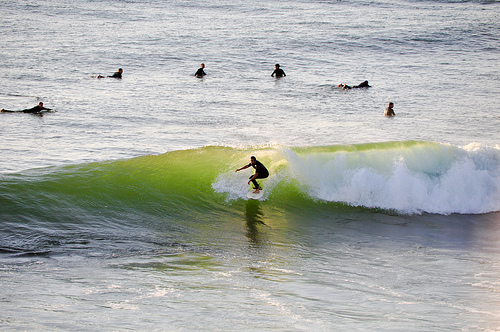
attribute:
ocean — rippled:
[13, 8, 495, 316]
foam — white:
[355, 154, 493, 215]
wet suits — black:
[1, 60, 396, 192]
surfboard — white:
[239, 186, 267, 210]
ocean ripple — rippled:
[393, 282, 411, 294]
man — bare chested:
[381, 98, 398, 117]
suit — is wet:
[249, 162, 267, 182]